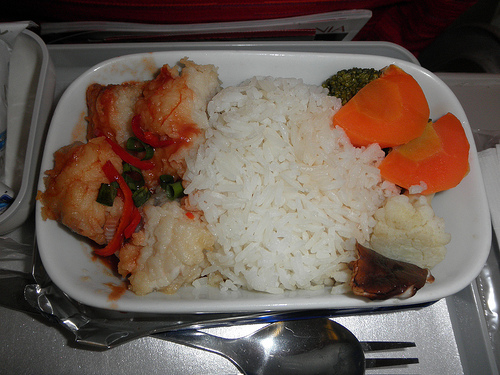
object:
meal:
[33, 55, 472, 300]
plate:
[34, 50, 492, 315]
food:
[333, 63, 430, 147]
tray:
[0, 29, 56, 235]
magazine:
[40, 9, 373, 42]